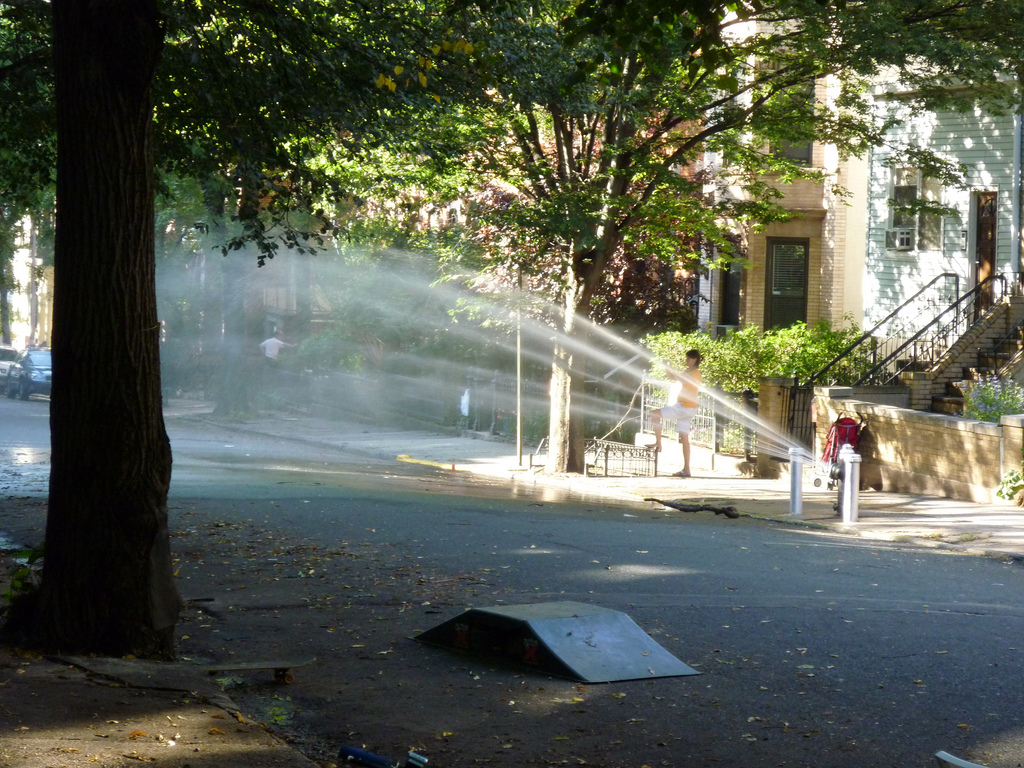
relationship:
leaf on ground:
[748, 707, 761, 717] [169, 526, 1006, 765]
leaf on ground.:
[793, 656, 813, 673] [2, 419, 1020, 761]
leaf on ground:
[796, 639, 816, 659] [170, 487, 1002, 747]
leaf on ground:
[820, 651, 843, 674] [170, 487, 1002, 747]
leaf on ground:
[824, 658, 838, 674] [170, 487, 1002, 747]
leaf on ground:
[508, 696, 516, 706] [169, 526, 1006, 765]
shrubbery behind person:
[629, 316, 871, 394] [659, 346, 716, 482]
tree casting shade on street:
[2, 0, 664, 665] [20, 351, 1001, 747]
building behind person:
[692, 0, 860, 484] [636, 328, 730, 495]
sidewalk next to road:
[0, 538, 329, 766] [68, 365, 1000, 763]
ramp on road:
[407, 595, 706, 688] [68, 365, 1000, 763]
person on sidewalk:
[659, 346, 707, 482] [165, 345, 993, 605]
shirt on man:
[249, 311, 316, 383] [255, 326, 304, 371]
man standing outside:
[255, 326, 295, 364] [37, 62, 1005, 763]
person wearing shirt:
[659, 346, 707, 482] [653, 354, 716, 415]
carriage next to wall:
[808, 406, 869, 499] [804, 382, 1018, 521]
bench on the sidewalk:
[581, 428, 671, 485] [193, 334, 1012, 590]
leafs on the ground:
[182, 513, 418, 625] [40, 427, 939, 763]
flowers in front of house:
[945, 367, 1022, 415] [772, 94, 1021, 473]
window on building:
[765, 238, 811, 330] [549, 77, 848, 410]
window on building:
[767, 238, 809, 333] [526, 71, 853, 417]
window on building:
[713, 247, 742, 327] [498, 66, 849, 438]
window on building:
[778, 61, 801, 156] [526, 71, 853, 417]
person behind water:
[659, 346, 707, 482] [151, 219, 871, 559]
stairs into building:
[777, 269, 1012, 456] [792, 148, 1022, 449]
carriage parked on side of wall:
[826, 414, 869, 492] [814, 407, 992, 505]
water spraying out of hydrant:
[57, 166, 831, 540] [818, 438, 867, 522]